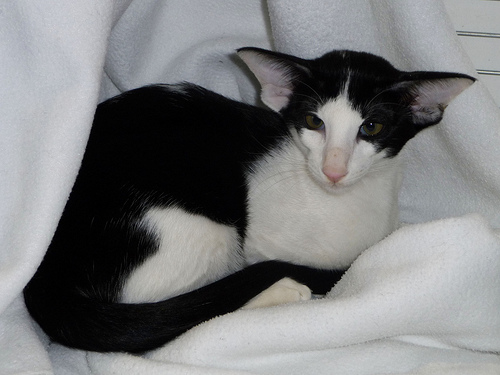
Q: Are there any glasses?
A: No, there are no glasses.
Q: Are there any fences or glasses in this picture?
A: No, there are no glasses or fences.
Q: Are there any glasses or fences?
A: No, there are no glasses or fences.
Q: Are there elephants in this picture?
A: No, there are no elephants.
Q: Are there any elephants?
A: No, there are no elephants.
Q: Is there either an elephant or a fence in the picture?
A: No, there are no elephants or fences.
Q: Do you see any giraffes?
A: No, there are no giraffes.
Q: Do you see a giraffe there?
A: No, there are no giraffes.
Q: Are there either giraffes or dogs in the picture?
A: No, there are no giraffes or dogs.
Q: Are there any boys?
A: No, there are no boys.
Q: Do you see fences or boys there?
A: No, there are no boys or fences.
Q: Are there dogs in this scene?
A: No, there are no dogs.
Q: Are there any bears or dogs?
A: No, there are no dogs or bears.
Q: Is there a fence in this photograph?
A: No, there are no fences.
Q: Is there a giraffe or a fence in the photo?
A: No, there are no fences or giraffes.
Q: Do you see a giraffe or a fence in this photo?
A: No, there are no fences or giraffes.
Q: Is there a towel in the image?
A: Yes, there is a towel.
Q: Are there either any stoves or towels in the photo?
A: Yes, there is a towel.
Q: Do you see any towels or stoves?
A: Yes, there is a towel.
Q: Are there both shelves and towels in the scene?
A: No, there is a towel but no shelves.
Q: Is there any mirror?
A: No, there are no mirrors.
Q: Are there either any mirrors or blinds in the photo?
A: No, there are no mirrors or blinds.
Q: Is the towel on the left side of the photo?
A: No, the towel is on the right of the image.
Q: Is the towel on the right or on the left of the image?
A: The towel is on the right of the image.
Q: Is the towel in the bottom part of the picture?
A: Yes, the towel is in the bottom of the image.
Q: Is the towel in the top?
A: No, the towel is in the bottom of the image.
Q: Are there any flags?
A: No, there are no flags.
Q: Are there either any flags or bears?
A: No, there are no flags or bears.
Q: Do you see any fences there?
A: No, there are no fences.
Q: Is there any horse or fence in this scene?
A: No, there are no fences or horses.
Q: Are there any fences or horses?
A: No, there are no fences or horses.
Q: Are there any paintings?
A: No, there are no paintings.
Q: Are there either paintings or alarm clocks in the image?
A: No, there are no paintings or alarm clocks.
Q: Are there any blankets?
A: Yes, there is a blanket.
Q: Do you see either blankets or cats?
A: Yes, there is a blanket.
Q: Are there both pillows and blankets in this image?
A: No, there is a blanket but no pillows.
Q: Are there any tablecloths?
A: No, there are no tablecloths.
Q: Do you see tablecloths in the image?
A: No, there are no tablecloths.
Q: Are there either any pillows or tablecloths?
A: No, there are no tablecloths or pillows.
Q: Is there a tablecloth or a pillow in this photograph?
A: No, there are no tablecloths or pillows.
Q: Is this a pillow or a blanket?
A: This is a blanket.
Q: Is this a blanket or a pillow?
A: This is a blanket.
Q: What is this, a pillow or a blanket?
A: This is a blanket.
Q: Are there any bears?
A: No, there are no bears.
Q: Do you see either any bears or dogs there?
A: No, there are no bears or dogs.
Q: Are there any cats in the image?
A: Yes, there is a cat.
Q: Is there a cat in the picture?
A: Yes, there is a cat.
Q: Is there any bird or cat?
A: Yes, there is a cat.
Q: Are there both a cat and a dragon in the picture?
A: No, there is a cat but no dragons.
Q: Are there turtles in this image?
A: No, there are no turtles.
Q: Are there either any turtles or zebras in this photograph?
A: No, there are no turtles or zebras.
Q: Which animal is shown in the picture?
A: The animal is a cat.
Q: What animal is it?
A: The animal is a cat.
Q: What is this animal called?
A: This is a cat.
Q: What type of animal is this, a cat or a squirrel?
A: This is a cat.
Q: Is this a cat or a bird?
A: This is a cat.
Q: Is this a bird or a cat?
A: This is a cat.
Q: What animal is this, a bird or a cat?
A: This is a cat.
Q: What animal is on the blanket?
A: The cat is on the blanket.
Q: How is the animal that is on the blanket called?
A: The animal is a cat.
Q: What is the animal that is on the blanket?
A: The animal is a cat.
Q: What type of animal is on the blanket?
A: The animal is a cat.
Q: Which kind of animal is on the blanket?
A: The animal is a cat.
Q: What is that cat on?
A: The cat is on the blanket.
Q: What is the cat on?
A: The cat is on the blanket.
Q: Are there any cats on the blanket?
A: Yes, there is a cat on the blanket.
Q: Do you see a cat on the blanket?
A: Yes, there is a cat on the blanket.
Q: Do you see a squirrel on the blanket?
A: No, there is a cat on the blanket.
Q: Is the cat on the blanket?
A: Yes, the cat is on the blanket.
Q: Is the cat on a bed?
A: No, the cat is on the blanket.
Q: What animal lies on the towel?
A: The animal is a cat.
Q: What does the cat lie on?
A: The cat lies on the towel.